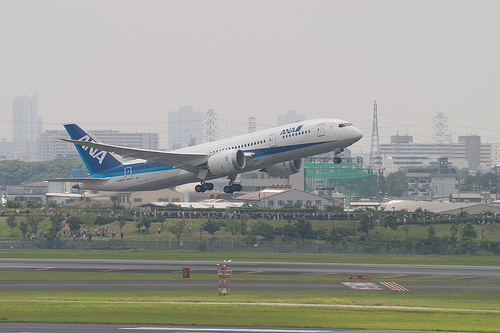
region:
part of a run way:
[380, 265, 405, 293]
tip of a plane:
[346, 126, 348, 140]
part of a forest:
[327, 210, 362, 267]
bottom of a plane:
[110, 179, 117, 188]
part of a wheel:
[226, 191, 251, 204]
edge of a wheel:
[205, 184, 214, 196]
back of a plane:
[106, 176, 118, 190]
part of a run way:
[331, 264, 351, 309]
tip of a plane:
[343, 110, 363, 145]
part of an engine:
[223, 138, 245, 172]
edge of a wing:
[149, 138, 211, 169]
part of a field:
[228, 283, 248, 311]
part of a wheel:
[169, 156, 206, 205]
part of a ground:
[233, 297, 245, 302]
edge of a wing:
[168, 146, 193, 162]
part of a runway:
[281, 273, 300, 291]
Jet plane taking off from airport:
[43, 55, 491, 313]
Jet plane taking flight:
[33, 67, 403, 256]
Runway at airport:
[41, 242, 455, 329]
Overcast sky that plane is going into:
[23, 5, 392, 216]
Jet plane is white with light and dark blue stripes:
[58, 105, 377, 206]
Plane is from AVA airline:
[247, 114, 320, 147]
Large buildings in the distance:
[3, 90, 490, 163]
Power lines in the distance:
[0, 99, 498, 159]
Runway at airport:
[158, 246, 433, 302]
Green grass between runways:
[0, 275, 442, 331]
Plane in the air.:
[48, 103, 365, 220]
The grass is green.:
[68, 289, 270, 326]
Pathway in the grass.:
[54, 290, 496, 319]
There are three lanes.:
[11, 248, 496, 331]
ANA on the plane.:
[66, 121, 118, 172]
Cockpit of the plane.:
[328, 117, 366, 148]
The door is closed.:
[262, 128, 287, 164]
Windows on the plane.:
[201, 135, 281, 156]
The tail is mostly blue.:
[57, 124, 124, 185]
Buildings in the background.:
[6, 92, 495, 217]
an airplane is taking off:
[31, 109, 378, 210]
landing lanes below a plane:
[1, 245, 498, 300]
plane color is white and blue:
[37, 93, 375, 201]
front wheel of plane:
[326, 148, 351, 167]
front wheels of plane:
[190, 178, 247, 198]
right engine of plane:
[263, 152, 304, 178]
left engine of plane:
[206, 142, 251, 179]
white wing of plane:
[55, 133, 210, 173]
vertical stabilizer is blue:
[58, 116, 123, 173]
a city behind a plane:
[9, 81, 494, 196]